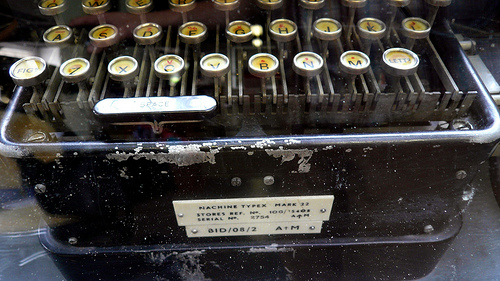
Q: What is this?
A: A typewriter.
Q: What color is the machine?
A: Black.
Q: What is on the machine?
A: Letters.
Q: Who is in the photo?
A: Nobody.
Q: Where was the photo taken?
A: In front of typewriter.